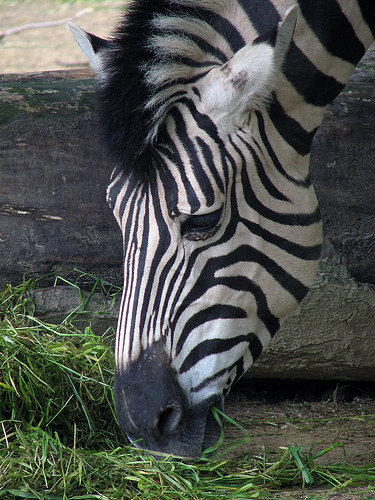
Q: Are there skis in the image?
A: No, there are no skis.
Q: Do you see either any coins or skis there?
A: No, there are no skis or coins.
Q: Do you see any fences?
A: No, there are no fences.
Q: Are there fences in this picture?
A: No, there are no fences.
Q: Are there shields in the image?
A: No, there are no shields.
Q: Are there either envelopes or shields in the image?
A: No, there are no shields or envelopes.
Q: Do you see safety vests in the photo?
A: No, there are no safety vests.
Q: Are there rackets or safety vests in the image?
A: No, there are no safety vests or rackets.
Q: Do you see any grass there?
A: Yes, there is grass.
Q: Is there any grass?
A: Yes, there is grass.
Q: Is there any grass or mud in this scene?
A: Yes, there is grass.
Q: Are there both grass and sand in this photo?
A: No, there is grass but no sand.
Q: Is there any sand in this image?
A: No, there is no sand.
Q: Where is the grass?
A: The grass is on the ground.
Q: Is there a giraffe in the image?
A: No, there are no giraffes.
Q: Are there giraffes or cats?
A: No, there are no giraffes or cats.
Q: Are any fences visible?
A: No, there are no fences.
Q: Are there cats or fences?
A: No, there are no fences or cats.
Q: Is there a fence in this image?
A: No, there are no fences.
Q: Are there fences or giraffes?
A: No, there are no fences or giraffes.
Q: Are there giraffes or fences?
A: No, there are no fences or giraffes.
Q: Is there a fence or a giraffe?
A: No, there are no fences or giraffes.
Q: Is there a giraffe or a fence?
A: No, there are no fences or giraffes.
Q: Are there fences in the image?
A: No, there are no fences.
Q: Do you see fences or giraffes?
A: No, there are no fences or giraffes.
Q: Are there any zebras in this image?
A: Yes, there is a zebra.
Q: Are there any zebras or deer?
A: Yes, there is a zebra.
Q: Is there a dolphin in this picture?
A: No, there are no dolphins.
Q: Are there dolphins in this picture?
A: No, there are no dolphins.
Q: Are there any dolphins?
A: No, there are no dolphins.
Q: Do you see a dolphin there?
A: No, there are no dolphins.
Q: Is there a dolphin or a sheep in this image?
A: No, there are no dolphins or sheep.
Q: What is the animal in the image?
A: The animal is a zebra.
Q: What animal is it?
A: The animal is a zebra.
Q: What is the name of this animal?
A: This is a zebra.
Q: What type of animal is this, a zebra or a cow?
A: This is a zebra.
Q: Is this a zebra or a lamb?
A: This is a zebra.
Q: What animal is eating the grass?
A: The zebra is eating the grass.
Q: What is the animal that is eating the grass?
A: The animal is a zebra.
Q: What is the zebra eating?
A: The zebra is eating grass.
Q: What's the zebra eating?
A: The zebra is eating grass.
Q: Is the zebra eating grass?
A: Yes, the zebra is eating grass.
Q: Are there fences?
A: No, there are no fences.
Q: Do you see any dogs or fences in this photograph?
A: No, there are no fences or dogs.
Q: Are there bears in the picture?
A: No, there are no bears.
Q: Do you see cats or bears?
A: No, there are no bears or cats.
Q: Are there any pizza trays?
A: No, there are no pizza trays.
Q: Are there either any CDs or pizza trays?
A: No, there are no pizza trays or cds.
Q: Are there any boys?
A: No, there are no boys.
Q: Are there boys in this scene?
A: No, there are no boys.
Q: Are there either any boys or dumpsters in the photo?
A: No, there are no boys or dumpsters.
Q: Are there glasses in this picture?
A: No, there are no glasses.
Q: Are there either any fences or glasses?
A: No, there are no glasses or fences.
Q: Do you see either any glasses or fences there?
A: No, there are no glasses or fences.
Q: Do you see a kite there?
A: No, there are no kites.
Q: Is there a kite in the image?
A: No, there are no kites.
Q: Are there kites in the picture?
A: No, there are no kites.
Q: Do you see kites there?
A: No, there are no kites.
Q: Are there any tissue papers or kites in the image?
A: No, there are no kites or tissue papers.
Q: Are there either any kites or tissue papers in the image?
A: No, there are no kites or tissue papers.